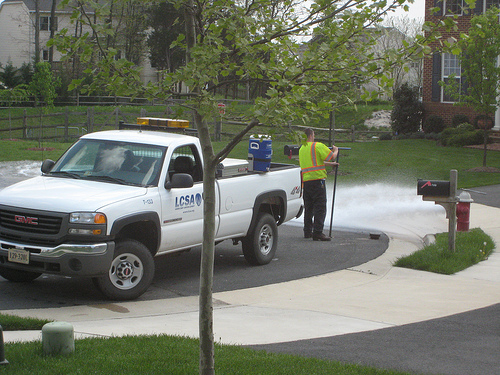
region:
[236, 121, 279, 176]
a blue cooler on the back of the truck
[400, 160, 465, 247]
a black mailbox on a postVisual Genome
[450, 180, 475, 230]
a red and white fire hyrdant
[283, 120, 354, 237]
a man in a yellow shirt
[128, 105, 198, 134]
lights on top of the truck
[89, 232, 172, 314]
front left tire on the truck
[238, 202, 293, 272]
back left tire on the truck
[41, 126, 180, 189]
front windshield on the truck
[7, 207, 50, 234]
the letters "GMC" on the front of the truck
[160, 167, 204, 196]
front left mirror on the truck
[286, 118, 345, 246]
Man wearing a green vest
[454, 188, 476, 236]
Fire hydrant on sidewalk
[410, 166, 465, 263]
Mail box is black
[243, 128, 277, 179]
Blue container on border of truck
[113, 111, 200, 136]
Orange lights on top of truck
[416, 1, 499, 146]
Building on left side of street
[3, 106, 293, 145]
Fence of wood is brown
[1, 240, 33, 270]
White plate in front of bumper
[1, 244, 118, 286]
Bumper is gray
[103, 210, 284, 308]
Wheels are black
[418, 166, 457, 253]
black mailbox on post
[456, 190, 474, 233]
red and white fire hydrant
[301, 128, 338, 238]
Worker in florescent green shirt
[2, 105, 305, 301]
white pickup truck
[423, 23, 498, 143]
brick building with black shutters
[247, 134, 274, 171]
blue cylindrical container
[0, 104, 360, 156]
wooden fence lining yard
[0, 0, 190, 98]
tan building with windows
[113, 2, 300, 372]
slim tree with green leaves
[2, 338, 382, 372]
patch of grass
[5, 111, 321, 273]
One white pick up truck.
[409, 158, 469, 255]
One black mailbox.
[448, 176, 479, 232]
One red fire hydrant.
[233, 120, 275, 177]
Blue cooler on the truck.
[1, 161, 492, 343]
Sidewalk made of concrete.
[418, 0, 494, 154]
House made of brick.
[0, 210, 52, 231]
The truck is a GMC.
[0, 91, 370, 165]
Fence lining the front yard.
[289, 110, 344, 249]
One man with a safety vest.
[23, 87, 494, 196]
The grass is green.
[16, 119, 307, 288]
the man has a white truck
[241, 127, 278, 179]
the truck has a blue cooler on the back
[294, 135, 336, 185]
the man is wearing a yellow work vest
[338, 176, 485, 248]
the fire hydrant is spewing water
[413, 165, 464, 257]
the mailbox is black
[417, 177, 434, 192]
the mailbox flag is red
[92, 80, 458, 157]
this house had a split rail fence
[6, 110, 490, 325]
this is a cul-de-sac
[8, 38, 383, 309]
the man is some kind of utility worker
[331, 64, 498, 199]
the yard is very well maintained